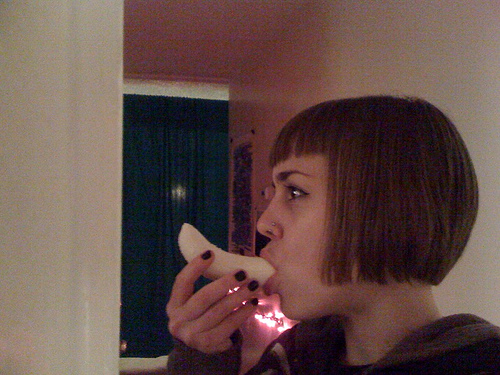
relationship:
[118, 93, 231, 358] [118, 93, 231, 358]
curtain hanging in curtain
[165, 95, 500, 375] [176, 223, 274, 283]
woman eating banana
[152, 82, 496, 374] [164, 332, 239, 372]
woman wearing long sleeve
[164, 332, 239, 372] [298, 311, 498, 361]
long sleeve with hood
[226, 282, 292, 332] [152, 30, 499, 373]
light behind woman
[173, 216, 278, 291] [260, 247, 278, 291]
banana in woman's mouth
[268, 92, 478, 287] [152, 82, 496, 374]
bobcut on woman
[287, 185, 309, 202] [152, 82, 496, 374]
eye of woman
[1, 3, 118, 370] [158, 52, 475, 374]
wall in front woman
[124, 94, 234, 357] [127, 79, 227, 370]
curtain hanging in doorway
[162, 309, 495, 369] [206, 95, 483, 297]
sweatshirt on woman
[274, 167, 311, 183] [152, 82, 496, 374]
eyebrow of woman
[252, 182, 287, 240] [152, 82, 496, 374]
nose of woman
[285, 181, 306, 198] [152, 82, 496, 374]
eye of woman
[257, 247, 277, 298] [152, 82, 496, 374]
lips on woman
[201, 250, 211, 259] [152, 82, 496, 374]
fingernail of woman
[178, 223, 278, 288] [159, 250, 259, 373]
banana in hand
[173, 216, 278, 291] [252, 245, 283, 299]
banana in womans mouth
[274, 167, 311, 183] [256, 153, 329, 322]
eyebrow on face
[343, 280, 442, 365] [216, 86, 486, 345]
neck on woman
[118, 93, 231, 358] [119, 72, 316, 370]
curtain covering window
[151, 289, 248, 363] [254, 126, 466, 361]
hand of woman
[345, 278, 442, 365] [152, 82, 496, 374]
neck of woman